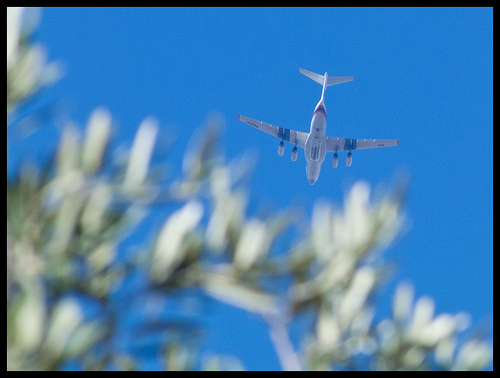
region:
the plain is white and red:
[312, 117, 324, 139]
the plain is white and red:
[314, 105, 321, 122]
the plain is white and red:
[327, 116, 333, 136]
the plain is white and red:
[311, 140, 325, 161]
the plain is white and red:
[311, 127, 327, 159]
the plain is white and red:
[311, 137, 316, 149]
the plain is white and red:
[308, 153, 317, 168]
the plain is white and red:
[321, 130, 329, 148]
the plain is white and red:
[315, 142, 320, 153]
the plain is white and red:
[312, 130, 320, 152]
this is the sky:
[174, 17, 246, 68]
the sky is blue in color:
[158, 7, 253, 79]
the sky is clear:
[103, 12, 262, 62]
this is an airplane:
[234, 60, 401, 185]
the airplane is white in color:
[315, 115, 325, 130]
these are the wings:
[238, 110, 398, 152]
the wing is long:
[325, 137, 402, 149]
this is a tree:
[32, 140, 132, 364]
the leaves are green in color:
[4, 212, 74, 291]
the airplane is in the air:
[236, 63, 406, 191]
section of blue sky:
[451, 157, 476, 177]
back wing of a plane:
[330, 77, 338, 84]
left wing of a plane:
[358, 140, 373, 150]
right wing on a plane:
[268, 128, 284, 140]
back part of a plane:
[323, 80, 326, 86]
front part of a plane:
[307, 176, 314, 189]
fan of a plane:
[281, 142, 286, 152]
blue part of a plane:
[346, 142, 358, 150]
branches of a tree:
[129, 190, 164, 222]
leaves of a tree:
[333, 300, 361, 323]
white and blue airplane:
[235, 66, 401, 186]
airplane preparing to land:
[235, 66, 400, 186]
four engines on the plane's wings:
[274, 140, 353, 168]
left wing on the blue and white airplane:
[237, 115, 309, 147]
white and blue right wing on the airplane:
[329, 135, 400, 150]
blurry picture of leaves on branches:
[6, 184, 493, 365]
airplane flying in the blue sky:
[235, 7, 499, 186]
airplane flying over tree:
[10, 6, 494, 371]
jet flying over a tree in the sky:
[230, 54, 408, 191]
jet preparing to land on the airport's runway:
[235, 64, 403, 187]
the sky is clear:
[425, 171, 446, 204]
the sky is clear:
[442, 165, 447, 190]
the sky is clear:
[395, 157, 415, 177]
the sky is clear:
[428, 216, 439, 237]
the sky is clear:
[423, 228, 429, 243]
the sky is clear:
[420, 250, 437, 267]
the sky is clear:
[446, 240, 456, 260]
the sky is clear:
[440, 180, 455, 200]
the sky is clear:
[436, 230, 451, 255]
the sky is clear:
[421, 242, 443, 272]